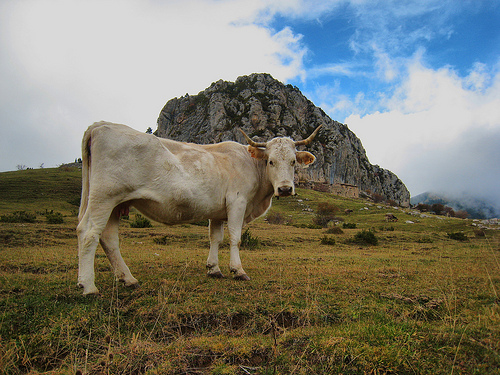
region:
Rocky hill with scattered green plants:
[149, 71, 411, 210]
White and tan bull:
[74, 115, 326, 297]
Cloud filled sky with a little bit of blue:
[4, 5, 496, 221]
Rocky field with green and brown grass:
[5, 159, 498, 371]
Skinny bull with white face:
[61, 114, 331, 297]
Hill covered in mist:
[404, 179, 499, 225]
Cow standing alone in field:
[6, 121, 498, 368]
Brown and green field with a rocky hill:
[8, 71, 498, 373]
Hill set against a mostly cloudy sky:
[0, 3, 497, 219]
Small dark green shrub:
[341, 232, 381, 249]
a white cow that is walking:
[72, 96, 314, 291]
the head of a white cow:
[254, 128, 319, 194]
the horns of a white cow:
[233, 119, 325, 151]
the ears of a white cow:
[248, 154, 323, 173]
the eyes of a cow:
[256, 156, 308, 173]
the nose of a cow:
[267, 173, 310, 198]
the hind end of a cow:
[53, 107, 147, 194]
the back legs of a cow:
[57, 175, 142, 288]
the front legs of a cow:
[213, 214, 273, 286]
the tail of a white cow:
[55, 119, 115, 194]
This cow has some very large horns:
[282, 111, 321, 160]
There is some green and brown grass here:
[389, 258, 405, 299]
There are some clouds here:
[388, 51, 440, 161]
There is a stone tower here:
[221, 84, 239, 114]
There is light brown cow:
[169, 135, 204, 217]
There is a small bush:
[25, 160, 36, 186]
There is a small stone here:
[393, 196, 430, 254]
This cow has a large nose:
[280, 177, 297, 205]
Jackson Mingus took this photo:
[121, 62, 358, 371]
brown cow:
[55, 118, 299, 242]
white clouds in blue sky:
[390, 28, 445, 85]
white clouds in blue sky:
[405, 76, 476, 133]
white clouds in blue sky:
[37, 29, 67, 60]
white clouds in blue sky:
[14, 59, 41, 91]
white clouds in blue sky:
[387, 89, 405, 103]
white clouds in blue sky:
[320, 31, 372, 63]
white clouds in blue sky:
[178, 9, 242, 43]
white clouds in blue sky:
[121, 46, 156, 73]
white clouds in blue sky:
[207, 0, 267, 48]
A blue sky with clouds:
[0, 1, 499, 216]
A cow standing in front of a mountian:
[75, 120, 322, 298]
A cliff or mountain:
[153, 71, 410, 208]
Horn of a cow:
[237, 126, 267, 147]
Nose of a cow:
[277, 183, 292, 195]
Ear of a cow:
[295, 150, 316, 167]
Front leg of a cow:
[225, 197, 250, 280]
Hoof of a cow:
[232, 273, 250, 281]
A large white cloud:
[0, 0, 346, 173]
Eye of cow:
[268, 159, 273, 165]